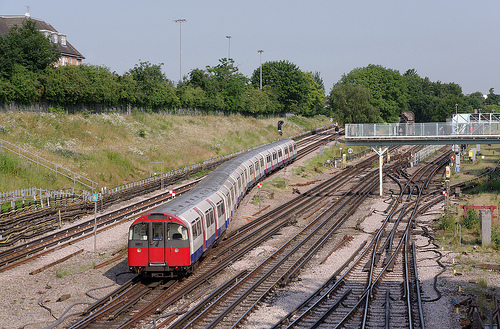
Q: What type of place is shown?
A: It is a station.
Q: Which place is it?
A: It is a station.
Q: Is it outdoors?
A: Yes, it is outdoors.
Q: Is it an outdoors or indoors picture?
A: It is outdoors.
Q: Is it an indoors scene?
A: No, it is outdoors.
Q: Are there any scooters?
A: No, there are no scooters.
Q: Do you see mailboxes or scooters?
A: No, there are no scooters or mailboxes.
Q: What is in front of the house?
A: The tree is in front of the house.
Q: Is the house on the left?
A: Yes, the house is on the left of the image.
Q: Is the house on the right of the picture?
A: No, the house is on the left of the image.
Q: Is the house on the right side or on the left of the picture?
A: The house is on the left of the image.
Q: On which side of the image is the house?
A: The house is on the left of the image.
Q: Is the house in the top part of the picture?
A: Yes, the house is in the top of the image.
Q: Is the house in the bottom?
A: No, the house is in the top of the image.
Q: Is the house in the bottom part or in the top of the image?
A: The house is in the top of the image.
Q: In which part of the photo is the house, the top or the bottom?
A: The house is in the top of the image.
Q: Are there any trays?
A: No, there are no trays.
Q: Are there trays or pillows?
A: No, there are no trays or pillows.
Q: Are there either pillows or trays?
A: No, there are no trays or pillows.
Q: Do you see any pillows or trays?
A: No, there are no trays or pillows.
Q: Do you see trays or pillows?
A: No, there are no trays or pillows.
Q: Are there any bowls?
A: No, there are no bowls.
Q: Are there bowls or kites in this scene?
A: No, there are no bowls or kites.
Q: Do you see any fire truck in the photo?
A: No, there are no fire trucks.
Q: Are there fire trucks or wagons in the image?
A: No, there are no fire trucks or wagons.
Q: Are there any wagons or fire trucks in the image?
A: No, there are no fire trucks or wagons.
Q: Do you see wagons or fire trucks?
A: No, there are no fire trucks or wagons.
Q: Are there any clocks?
A: No, there are no clocks.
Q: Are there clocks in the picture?
A: No, there are no clocks.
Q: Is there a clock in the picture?
A: No, there are no clocks.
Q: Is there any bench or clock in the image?
A: No, there are no clocks or benches.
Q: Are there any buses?
A: No, there are no buses.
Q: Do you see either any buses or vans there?
A: No, there are no buses or vans.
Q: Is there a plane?
A: No, there are no airplanes.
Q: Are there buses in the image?
A: No, there are no buses.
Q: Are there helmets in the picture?
A: No, there are no helmets.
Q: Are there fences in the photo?
A: Yes, there is a fence.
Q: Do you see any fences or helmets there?
A: Yes, there is a fence.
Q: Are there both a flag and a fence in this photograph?
A: Yes, there are both a fence and a flag.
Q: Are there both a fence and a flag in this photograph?
A: Yes, there are both a fence and a flag.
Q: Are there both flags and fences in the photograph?
A: Yes, there are both a fence and a flag.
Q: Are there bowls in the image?
A: No, there are no bowls.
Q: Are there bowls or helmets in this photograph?
A: No, there are no bowls or helmets.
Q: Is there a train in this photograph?
A: Yes, there is a train.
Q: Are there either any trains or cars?
A: Yes, there is a train.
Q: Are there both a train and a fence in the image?
A: Yes, there are both a train and a fence.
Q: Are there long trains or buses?
A: Yes, there is a long train.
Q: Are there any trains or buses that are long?
A: Yes, the train is long.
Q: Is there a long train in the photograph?
A: Yes, there is a long train.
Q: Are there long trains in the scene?
A: Yes, there is a long train.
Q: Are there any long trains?
A: Yes, there is a long train.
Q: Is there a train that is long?
A: Yes, there is a train that is long.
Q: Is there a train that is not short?
A: Yes, there is a long train.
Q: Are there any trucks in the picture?
A: No, there are no trucks.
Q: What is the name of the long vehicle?
A: The vehicle is a train.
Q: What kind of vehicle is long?
A: The vehicle is a train.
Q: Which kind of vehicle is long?
A: The vehicle is a train.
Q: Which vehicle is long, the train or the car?
A: The train is long.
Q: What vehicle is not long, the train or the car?
A: The car is not long.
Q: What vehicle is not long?
A: The vehicle is a car.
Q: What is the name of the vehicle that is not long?
A: The vehicle is a car.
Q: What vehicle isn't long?
A: The vehicle is a car.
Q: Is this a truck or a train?
A: This is a train.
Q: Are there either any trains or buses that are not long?
A: No, there is a train but it is long.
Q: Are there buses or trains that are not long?
A: No, there is a train but it is long.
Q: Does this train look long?
A: Yes, the train is long.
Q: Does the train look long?
A: Yes, the train is long.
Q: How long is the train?
A: The train is long.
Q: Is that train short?
A: No, the train is long.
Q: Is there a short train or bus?
A: No, there is a train but it is long.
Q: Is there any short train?
A: No, there is a train but it is long.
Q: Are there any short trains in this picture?
A: No, there is a train but it is long.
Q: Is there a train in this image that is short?
A: No, there is a train but it is long.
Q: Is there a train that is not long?
A: No, there is a train but it is long.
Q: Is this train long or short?
A: The train is long.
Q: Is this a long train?
A: Yes, this is a long train.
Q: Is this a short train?
A: No, this is a long train.